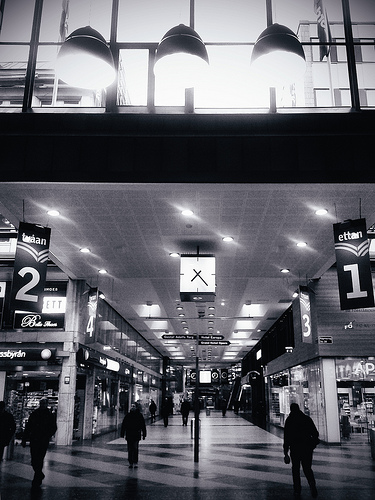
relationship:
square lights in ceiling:
[238, 301, 266, 318] [0, 182, 368, 364]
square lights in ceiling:
[230, 317, 263, 331] [0, 182, 368, 364]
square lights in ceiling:
[226, 328, 255, 340] [0, 182, 368, 364]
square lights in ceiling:
[126, 301, 164, 319] [0, 182, 368, 364]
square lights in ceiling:
[140, 318, 172, 331] [0, 182, 368, 364]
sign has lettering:
[160, 328, 194, 342] [200, 334, 223, 339]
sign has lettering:
[199, 333, 223, 338] [200, 334, 223, 339]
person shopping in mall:
[99, 397, 152, 480] [1, 182, 373, 499]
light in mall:
[298, 240, 306, 247] [0, 0, 373, 499]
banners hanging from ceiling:
[7, 221, 49, 331] [0, 182, 368, 364]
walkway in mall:
[69, 417, 337, 487] [0, 0, 373, 499]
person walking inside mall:
[281, 403, 321, 500] [0, 0, 373, 499]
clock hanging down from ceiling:
[178, 253, 217, 306] [3, 184, 373, 387]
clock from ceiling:
[178, 255, 215, 295] [0, 182, 368, 364]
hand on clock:
[195, 269, 208, 286] [180, 252, 215, 302]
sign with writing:
[160, 334, 194, 342] [163, 331, 198, 340]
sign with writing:
[198, 333, 224, 338] [194, 333, 228, 342]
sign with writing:
[198, 341, 231, 345] [193, 337, 229, 346]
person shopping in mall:
[281, 403, 320, 498] [0, 0, 373, 499]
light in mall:
[216, 328, 219, 333] [0, 0, 373, 499]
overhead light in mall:
[167, 302, 187, 313] [0, 0, 373, 499]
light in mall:
[179, 315, 188, 326] [43, 204, 333, 490]